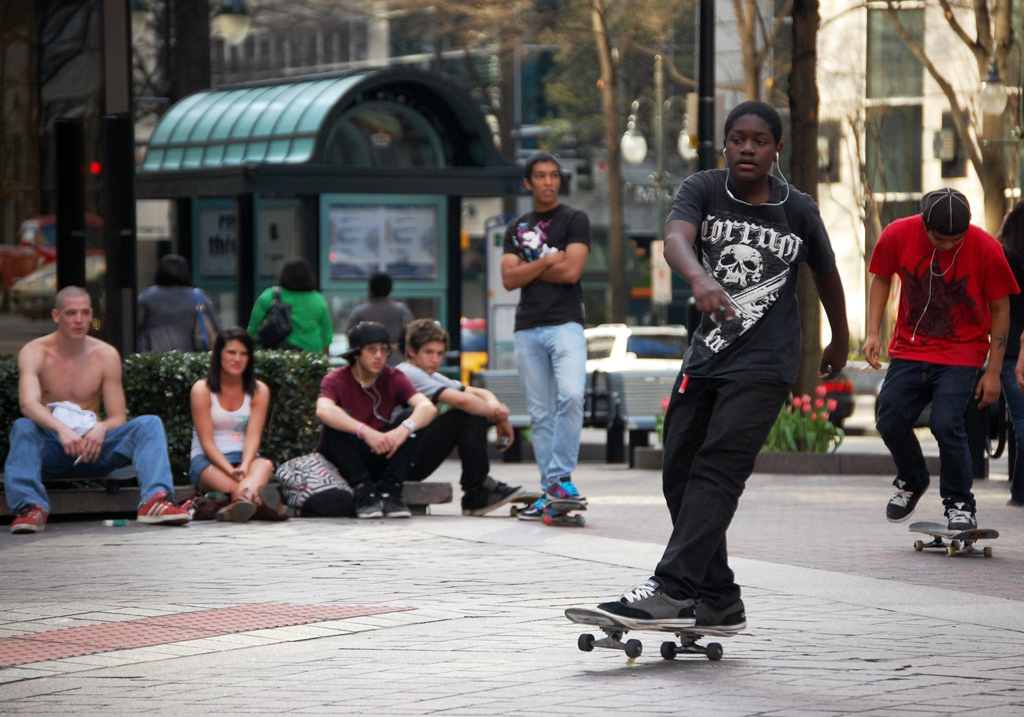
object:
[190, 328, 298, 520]
woman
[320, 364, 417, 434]
shirt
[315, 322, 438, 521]
man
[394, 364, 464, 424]
shirt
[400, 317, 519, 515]
man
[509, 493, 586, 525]
skateboard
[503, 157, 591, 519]
man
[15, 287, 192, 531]
man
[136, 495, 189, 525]
shoes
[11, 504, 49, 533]
shoes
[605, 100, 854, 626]
boy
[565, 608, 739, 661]
skateboard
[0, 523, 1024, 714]
floor